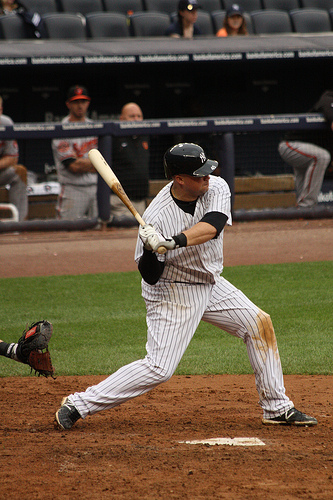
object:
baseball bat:
[87, 147, 166, 255]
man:
[55, 141, 318, 431]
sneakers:
[261, 405, 318, 426]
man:
[51, 83, 99, 219]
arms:
[54, 139, 94, 174]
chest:
[68, 127, 98, 160]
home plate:
[176, 437, 266, 447]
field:
[0, 218, 332, 498]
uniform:
[66, 173, 295, 420]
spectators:
[163, 0, 201, 38]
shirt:
[109, 128, 150, 204]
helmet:
[183, 144, 225, 178]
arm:
[148, 188, 231, 256]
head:
[164, 141, 210, 196]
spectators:
[215, 4, 251, 37]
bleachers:
[0, 0, 333, 40]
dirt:
[249, 309, 281, 364]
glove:
[145, 231, 187, 255]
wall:
[0, 51, 333, 186]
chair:
[42, 14, 86, 40]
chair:
[85, 12, 130, 38]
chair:
[129, 14, 171, 38]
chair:
[250, 10, 293, 34]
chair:
[289, 8, 331, 33]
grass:
[0, 258, 332, 376]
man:
[105, 100, 151, 223]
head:
[120, 102, 143, 120]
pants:
[68, 274, 296, 423]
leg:
[56, 286, 199, 428]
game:
[0, 0, 331, 500]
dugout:
[0, 64, 332, 224]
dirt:
[0, 375, 332, 499]